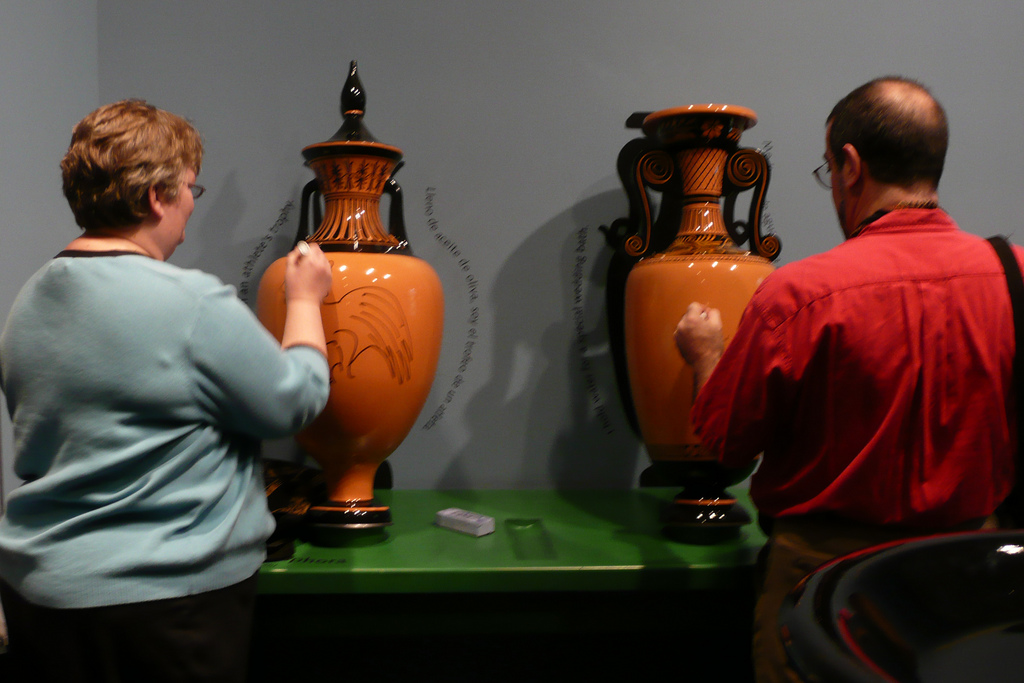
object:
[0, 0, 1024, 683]
inside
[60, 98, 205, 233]
hair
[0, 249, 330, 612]
shirt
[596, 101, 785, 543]
pot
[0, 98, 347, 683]
person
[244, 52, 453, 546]
pot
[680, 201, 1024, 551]
shirt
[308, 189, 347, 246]
stripe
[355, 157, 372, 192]
stripe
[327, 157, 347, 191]
stripe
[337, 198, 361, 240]
stripe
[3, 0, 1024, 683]
picture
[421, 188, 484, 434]
lettering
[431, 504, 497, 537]
box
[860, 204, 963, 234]
string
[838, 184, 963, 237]
man's neck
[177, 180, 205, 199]
glasses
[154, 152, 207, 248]
woman's face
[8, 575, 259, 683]
pants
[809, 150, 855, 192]
glasses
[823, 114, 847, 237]
man's face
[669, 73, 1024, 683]
man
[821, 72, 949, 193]
hair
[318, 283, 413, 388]
design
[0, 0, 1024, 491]
wall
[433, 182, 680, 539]
shadow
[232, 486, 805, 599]
table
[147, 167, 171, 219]
ear